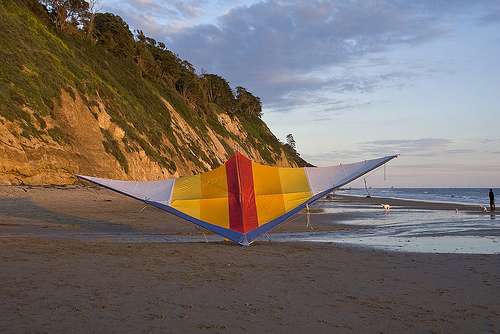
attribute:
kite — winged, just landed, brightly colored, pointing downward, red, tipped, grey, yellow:
[74, 148, 399, 246]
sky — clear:
[62, 0, 499, 188]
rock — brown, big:
[104, 199, 111, 206]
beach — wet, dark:
[0, 190, 499, 333]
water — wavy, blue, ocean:
[333, 186, 500, 207]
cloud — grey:
[163, 0, 493, 114]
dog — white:
[379, 202, 392, 214]